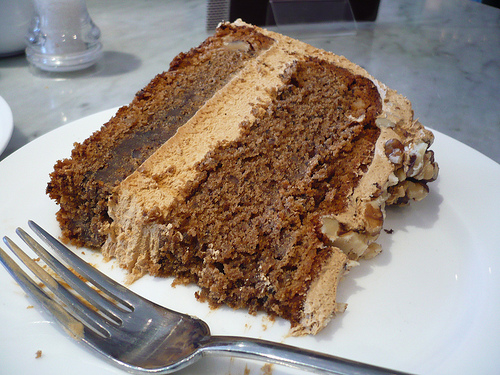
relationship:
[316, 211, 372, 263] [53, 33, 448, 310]
walnut on top of cake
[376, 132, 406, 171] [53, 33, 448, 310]
walnut on top of cake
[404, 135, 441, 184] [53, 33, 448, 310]
walnut on top of cake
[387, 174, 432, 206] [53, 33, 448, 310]
walnut on top of cake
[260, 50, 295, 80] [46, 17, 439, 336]
icing inside cake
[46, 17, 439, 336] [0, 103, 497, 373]
cake on plate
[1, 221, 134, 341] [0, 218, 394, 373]
prong on fork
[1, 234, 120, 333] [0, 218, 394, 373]
prong on fork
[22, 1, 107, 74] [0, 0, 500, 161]
container on table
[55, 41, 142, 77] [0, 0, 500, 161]
shadow on table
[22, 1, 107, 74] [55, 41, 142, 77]
container casting shadow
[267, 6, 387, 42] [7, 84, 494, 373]
document holder on table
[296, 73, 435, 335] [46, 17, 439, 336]
frosting on cake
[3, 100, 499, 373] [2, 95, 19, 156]
saucer has edge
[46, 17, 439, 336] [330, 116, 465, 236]
cake has nuts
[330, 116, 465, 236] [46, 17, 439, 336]
nuts are on cake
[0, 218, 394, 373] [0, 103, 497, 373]
fork sits on plate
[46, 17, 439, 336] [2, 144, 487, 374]
cake on plate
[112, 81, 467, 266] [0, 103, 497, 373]
cake on plate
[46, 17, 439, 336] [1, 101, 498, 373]
cake on white plate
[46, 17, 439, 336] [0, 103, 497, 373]
cake served on plate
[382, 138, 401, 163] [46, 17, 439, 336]
nuts on cake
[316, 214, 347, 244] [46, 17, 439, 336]
nuts on cake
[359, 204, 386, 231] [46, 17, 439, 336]
nuts on cake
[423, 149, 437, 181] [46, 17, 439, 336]
nuts on cake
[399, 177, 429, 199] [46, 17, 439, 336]
nuts on cake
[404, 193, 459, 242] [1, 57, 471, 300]
shadow on plate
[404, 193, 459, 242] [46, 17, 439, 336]
shadow of cake